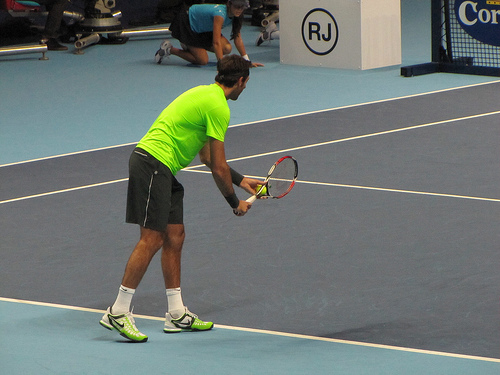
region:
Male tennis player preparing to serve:
[96, 50, 266, 340]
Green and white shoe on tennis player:
[155, 310, 210, 330]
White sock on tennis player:
[160, 285, 180, 315]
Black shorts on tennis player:
[121, 145, 181, 226]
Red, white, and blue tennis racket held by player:
[247, 151, 297, 201]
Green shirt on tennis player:
[133, 80, 230, 173]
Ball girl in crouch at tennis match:
[151, 0, 265, 71]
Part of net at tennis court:
[398, 0, 499, 77]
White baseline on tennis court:
[1, 253, 499, 362]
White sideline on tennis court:
[1, 107, 499, 204]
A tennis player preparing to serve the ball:
[102, 55, 303, 337]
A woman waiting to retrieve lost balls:
[154, 4, 268, 73]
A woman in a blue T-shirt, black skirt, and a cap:
[154, 6, 260, 67]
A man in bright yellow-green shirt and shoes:
[102, 56, 294, 338]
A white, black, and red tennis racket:
[231, 150, 314, 215]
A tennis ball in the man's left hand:
[251, 181, 271, 199]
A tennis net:
[428, 1, 498, 78]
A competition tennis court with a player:
[5, 82, 496, 359]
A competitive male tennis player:
[103, 50, 304, 330]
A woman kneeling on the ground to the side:
[157, 2, 266, 70]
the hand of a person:
[202, 114, 253, 224]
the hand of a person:
[198, 137, 271, 194]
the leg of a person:
[156, 182, 218, 333]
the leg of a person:
[96, 181, 165, 349]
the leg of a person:
[154, 40, 209, 74]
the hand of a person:
[207, 8, 227, 61]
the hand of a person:
[233, 17, 260, 65]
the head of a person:
[216, 46, 256, 93]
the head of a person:
[226, 0, 245, 25]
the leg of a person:
[206, 27, 233, 52]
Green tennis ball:
[253, 180, 271, 200]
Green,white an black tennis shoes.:
[93, 287, 229, 368]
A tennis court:
[88, 50, 449, 372]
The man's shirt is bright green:
[160, 84, 240, 170]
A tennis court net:
[436, 21, 481, 91]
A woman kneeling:
[158, 12, 295, 66]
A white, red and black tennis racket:
[238, 155, 355, 243]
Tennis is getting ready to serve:
[145, 48, 270, 346]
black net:
[452, 0, 497, 67]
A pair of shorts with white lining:
[132, 157, 190, 237]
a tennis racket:
[234, 147, 316, 218]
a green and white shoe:
[91, 299, 156, 346]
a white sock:
[105, 276, 133, 314]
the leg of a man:
[105, 159, 170, 318]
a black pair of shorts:
[120, 139, 188, 236]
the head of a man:
[208, 51, 263, 102]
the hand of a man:
[228, 196, 263, 220]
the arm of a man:
[206, 110, 245, 210]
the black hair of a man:
[208, 49, 255, 91]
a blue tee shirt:
[187, 0, 232, 41]